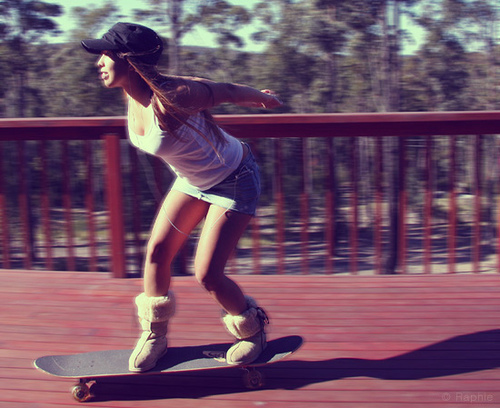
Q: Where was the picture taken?
A: On a deck.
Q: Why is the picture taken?
A: To capture the women skateboarding.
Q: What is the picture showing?
A: A women on a skateboard.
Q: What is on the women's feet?
A: Boots.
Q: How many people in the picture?
A: One.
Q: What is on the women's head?
A: A hat.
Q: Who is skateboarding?
A: A women.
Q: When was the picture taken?
A: During the day.